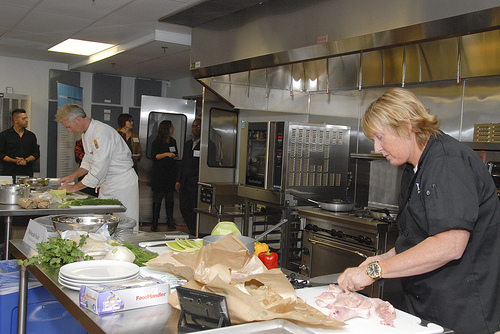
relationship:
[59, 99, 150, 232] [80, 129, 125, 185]
chef in all white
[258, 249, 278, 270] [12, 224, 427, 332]
pepper laying on table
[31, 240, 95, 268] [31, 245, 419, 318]
green lettuce on table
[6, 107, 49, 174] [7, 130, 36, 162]
man standing wearing all black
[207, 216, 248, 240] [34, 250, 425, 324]
mixing bowl laying on table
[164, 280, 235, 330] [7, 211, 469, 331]
ipod on table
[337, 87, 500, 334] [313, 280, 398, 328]
man cutting meat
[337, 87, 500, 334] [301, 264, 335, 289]
man using a knife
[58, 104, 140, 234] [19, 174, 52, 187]
chef cooking food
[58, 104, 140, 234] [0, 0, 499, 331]
chef in kitchen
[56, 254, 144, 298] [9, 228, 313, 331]
plate stack on table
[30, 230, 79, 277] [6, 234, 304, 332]
leaves on table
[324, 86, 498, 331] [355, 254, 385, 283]
man wearing a watch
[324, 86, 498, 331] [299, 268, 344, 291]
man with a knife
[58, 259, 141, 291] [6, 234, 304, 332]
plate stack on table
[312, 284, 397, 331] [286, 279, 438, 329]
meat on cutting board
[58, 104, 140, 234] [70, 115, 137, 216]
chef in outfit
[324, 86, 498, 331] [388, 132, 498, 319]
man in outfit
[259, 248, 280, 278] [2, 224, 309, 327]
pepper on table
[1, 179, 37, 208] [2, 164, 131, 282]
pot on table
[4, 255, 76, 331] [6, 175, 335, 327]
trasn can on ground